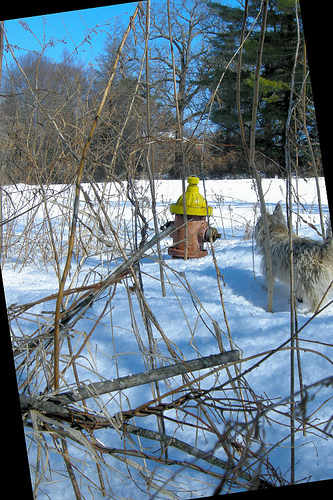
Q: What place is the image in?
A: It is at the field.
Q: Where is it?
A: This is at the field.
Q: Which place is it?
A: It is a field.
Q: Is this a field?
A: Yes, it is a field.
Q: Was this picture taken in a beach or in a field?
A: It was taken at a field.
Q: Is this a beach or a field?
A: It is a field.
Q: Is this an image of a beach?
A: No, the picture is showing a field.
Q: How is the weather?
A: It is sunny.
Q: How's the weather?
A: It is sunny.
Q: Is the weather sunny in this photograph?
A: Yes, it is sunny.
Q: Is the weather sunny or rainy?
A: It is sunny.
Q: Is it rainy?
A: No, it is sunny.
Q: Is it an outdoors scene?
A: Yes, it is outdoors.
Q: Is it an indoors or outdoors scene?
A: It is outdoors.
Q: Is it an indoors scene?
A: No, it is outdoors.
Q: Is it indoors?
A: No, it is outdoors.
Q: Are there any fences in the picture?
A: No, there are no fences.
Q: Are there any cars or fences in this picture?
A: No, there are no fences or cars.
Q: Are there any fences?
A: No, there are no fences.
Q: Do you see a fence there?
A: No, there are no fences.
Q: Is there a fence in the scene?
A: No, there are no fences.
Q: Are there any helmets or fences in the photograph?
A: No, there are no fences or helmets.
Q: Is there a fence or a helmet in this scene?
A: No, there are no fences or helmets.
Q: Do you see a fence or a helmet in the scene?
A: No, there are no fences or helmets.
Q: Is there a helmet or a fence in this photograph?
A: No, there are no fences or helmets.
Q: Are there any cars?
A: No, there are no cars.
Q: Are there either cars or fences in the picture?
A: No, there are no cars or fences.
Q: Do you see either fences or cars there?
A: No, there are no cars or fences.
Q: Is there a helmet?
A: No, there are no helmets.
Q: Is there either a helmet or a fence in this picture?
A: No, there are no helmets or fences.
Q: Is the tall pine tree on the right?
A: Yes, the pine is on the right of the image.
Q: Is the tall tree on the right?
A: Yes, the pine is on the right of the image.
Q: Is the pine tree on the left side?
A: No, the pine tree is on the right of the image.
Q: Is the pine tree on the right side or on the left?
A: The pine tree is on the right of the image.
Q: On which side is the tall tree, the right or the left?
A: The pine tree is on the right of the image.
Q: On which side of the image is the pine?
A: The pine is on the right of the image.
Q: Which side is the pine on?
A: The pine is on the right of the image.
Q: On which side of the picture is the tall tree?
A: The pine is on the right of the image.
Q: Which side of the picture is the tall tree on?
A: The pine is on the right of the image.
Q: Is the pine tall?
A: Yes, the pine is tall.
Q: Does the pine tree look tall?
A: Yes, the pine tree is tall.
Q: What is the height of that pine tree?
A: The pine tree is tall.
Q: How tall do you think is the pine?
A: The pine is tall.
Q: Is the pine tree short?
A: No, the pine tree is tall.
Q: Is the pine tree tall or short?
A: The pine tree is tall.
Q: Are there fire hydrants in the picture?
A: Yes, there is a fire hydrant.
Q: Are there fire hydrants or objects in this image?
A: Yes, there is a fire hydrant.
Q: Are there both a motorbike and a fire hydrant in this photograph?
A: No, there is a fire hydrant but no motorcycles.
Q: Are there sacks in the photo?
A: No, there are no sacks.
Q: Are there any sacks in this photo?
A: No, there are no sacks.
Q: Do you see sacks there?
A: No, there are no sacks.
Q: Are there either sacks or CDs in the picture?
A: No, there are no sacks or cds.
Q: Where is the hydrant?
A: The hydrant is in the field.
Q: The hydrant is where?
A: The hydrant is in the field.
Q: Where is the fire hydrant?
A: The hydrant is in the field.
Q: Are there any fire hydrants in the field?
A: Yes, there is a fire hydrant in the field.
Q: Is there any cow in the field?
A: No, there is a fire hydrant in the field.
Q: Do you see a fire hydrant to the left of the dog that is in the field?
A: Yes, there is a fire hydrant to the left of the dog.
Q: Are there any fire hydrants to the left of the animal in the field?
A: Yes, there is a fire hydrant to the left of the dog.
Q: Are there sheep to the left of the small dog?
A: No, there is a fire hydrant to the left of the dog.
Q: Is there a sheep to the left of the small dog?
A: No, there is a fire hydrant to the left of the dog.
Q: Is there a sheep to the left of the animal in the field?
A: No, there is a fire hydrant to the left of the dog.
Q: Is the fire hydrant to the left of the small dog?
A: Yes, the fire hydrant is to the left of the dog.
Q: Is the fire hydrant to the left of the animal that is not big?
A: Yes, the fire hydrant is to the left of the dog.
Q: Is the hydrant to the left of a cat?
A: No, the hydrant is to the left of the dog.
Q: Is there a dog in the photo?
A: Yes, there is a dog.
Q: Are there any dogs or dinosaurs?
A: Yes, there is a dog.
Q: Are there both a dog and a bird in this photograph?
A: No, there is a dog but no birds.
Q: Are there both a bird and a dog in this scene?
A: No, there is a dog but no birds.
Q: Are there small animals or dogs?
A: Yes, there is a small dog.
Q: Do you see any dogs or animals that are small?
A: Yes, the dog is small.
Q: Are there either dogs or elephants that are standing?
A: Yes, the dog is standing.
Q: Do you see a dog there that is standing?
A: Yes, there is a dog that is standing.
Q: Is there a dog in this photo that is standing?
A: Yes, there is a dog that is standing.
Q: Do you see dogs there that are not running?
A: Yes, there is a dog that is standing .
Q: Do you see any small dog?
A: Yes, there is a small dog.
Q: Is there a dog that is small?
A: Yes, there is a dog that is small.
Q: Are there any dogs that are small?
A: Yes, there is a dog that is small.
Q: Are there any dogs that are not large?
A: Yes, there is a small dog.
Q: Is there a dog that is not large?
A: Yes, there is a small dog.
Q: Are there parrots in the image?
A: No, there are no parrots.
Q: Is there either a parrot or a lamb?
A: No, there are no parrots or lambs.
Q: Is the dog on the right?
A: Yes, the dog is on the right of the image.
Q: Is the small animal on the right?
A: Yes, the dog is on the right of the image.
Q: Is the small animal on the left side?
A: No, the dog is on the right of the image.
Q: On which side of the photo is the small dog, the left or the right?
A: The dog is on the right of the image.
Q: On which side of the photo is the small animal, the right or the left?
A: The dog is on the right of the image.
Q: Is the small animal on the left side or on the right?
A: The dog is on the right of the image.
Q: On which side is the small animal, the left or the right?
A: The dog is on the right of the image.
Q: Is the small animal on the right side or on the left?
A: The dog is on the right of the image.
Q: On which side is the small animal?
A: The dog is on the right of the image.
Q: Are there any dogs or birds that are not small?
A: No, there is a dog but it is small.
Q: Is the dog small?
A: Yes, the dog is small.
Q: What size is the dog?
A: The dog is small.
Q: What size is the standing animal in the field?
A: The dog is small.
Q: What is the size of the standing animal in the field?
A: The dog is small.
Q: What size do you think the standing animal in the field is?
A: The dog is small.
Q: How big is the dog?
A: The dog is small.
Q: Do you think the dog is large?
A: No, the dog is small.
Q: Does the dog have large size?
A: No, the dog is small.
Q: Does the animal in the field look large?
A: No, the dog is small.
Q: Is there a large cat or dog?
A: No, there is a dog but it is small.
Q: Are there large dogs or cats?
A: No, there is a dog but it is small.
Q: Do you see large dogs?
A: No, there is a dog but it is small.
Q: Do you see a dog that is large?
A: No, there is a dog but it is small.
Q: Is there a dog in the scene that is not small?
A: No, there is a dog but it is small.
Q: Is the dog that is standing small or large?
A: The dog is small.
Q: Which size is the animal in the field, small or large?
A: The dog is small.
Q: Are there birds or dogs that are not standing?
A: No, there is a dog but it is standing.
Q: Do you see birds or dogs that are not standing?
A: No, there is a dog but it is standing.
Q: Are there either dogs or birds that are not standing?
A: No, there is a dog but it is standing.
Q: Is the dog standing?
A: Yes, the dog is standing.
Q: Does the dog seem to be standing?
A: Yes, the dog is standing.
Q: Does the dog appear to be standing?
A: Yes, the dog is standing.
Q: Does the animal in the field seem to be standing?
A: Yes, the dog is standing.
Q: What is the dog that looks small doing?
A: The dog is standing.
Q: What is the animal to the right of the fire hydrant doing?
A: The dog is standing.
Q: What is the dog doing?
A: The dog is standing.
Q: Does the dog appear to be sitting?
A: No, the dog is standing.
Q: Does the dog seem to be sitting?
A: No, the dog is standing.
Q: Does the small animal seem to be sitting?
A: No, the dog is standing.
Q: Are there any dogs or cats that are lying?
A: No, there is a dog but it is standing.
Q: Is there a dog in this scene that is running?
A: No, there is a dog but it is standing.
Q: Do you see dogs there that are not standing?
A: No, there is a dog but it is standing.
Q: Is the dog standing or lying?
A: The dog is standing.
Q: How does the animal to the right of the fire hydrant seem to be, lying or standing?
A: The dog is standing.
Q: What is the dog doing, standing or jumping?
A: The dog is standing.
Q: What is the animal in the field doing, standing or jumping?
A: The dog is standing.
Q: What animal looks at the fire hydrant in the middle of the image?
A: The dog looks at the hydrant.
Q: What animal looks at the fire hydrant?
A: The dog looks at the hydrant.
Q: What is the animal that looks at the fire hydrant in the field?
A: The animal is a dog.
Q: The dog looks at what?
A: The dog looks at the fire hydrant.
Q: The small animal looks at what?
A: The dog looks at the fire hydrant.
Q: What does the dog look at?
A: The dog looks at the fire hydrant.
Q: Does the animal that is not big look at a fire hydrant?
A: Yes, the dog looks at a fire hydrant.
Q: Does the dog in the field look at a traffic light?
A: No, the dog looks at a fire hydrant.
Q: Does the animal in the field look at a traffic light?
A: No, the dog looks at a fire hydrant.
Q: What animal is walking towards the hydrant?
A: The dog is walking towards the hydrant.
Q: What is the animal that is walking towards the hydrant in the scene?
A: The animal is a dog.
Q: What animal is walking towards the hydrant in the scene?
A: The animal is a dog.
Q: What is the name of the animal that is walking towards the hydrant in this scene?
A: The animal is a dog.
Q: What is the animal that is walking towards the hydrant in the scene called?
A: The animal is a dog.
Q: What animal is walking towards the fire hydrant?
A: The animal is a dog.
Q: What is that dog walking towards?
A: The dog is walking towards the hydrant.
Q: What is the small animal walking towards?
A: The dog is walking towards the hydrant.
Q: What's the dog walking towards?
A: The dog is walking towards the hydrant.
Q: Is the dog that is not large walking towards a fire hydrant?
A: Yes, the dog is walking towards a fire hydrant.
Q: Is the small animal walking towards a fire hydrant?
A: Yes, the dog is walking towards a fire hydrant.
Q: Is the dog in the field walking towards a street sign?
A: No, the dog is walking towards a fire hydrant.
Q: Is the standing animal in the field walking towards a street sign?
A: No, the dog is walking towards a fire hydrant.